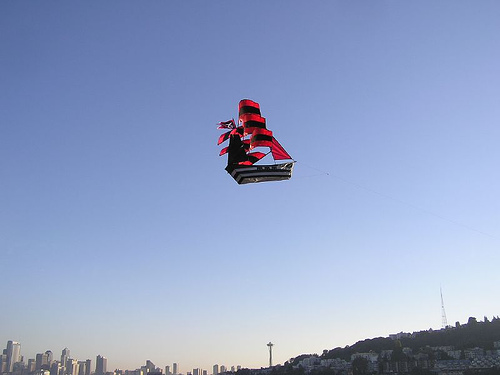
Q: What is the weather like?
A: It is clear.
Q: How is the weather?
A: It is clear.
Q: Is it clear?
A: Yes, it is clear.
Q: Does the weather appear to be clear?
A: Yes, it is clear.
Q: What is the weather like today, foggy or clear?
A: It is clear.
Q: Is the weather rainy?
A: No, it is clear.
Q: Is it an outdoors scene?
A: Yes, it is outdoors.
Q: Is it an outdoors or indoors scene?
A: It is outdoors.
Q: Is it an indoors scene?
A: No, it is outdoors.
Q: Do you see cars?
A: No, there are no cars.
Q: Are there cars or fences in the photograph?
A: No, there are no cars or fences.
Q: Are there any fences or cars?
A: No, there are no cars or fences.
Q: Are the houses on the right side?
A: Yes, the houses are on the right of the image.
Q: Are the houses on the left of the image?
A: No, the houses are on the right of the image.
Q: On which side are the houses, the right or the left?
A: The houses are on the right of the image.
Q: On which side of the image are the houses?
A: The houses are on the right of the image.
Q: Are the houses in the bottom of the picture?
A: Yes, the houses are in the bottom of the image.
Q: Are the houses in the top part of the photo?
A: No, the houses are in the bottom of the image.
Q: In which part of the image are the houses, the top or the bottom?
A: The houses are in the bottom of the image.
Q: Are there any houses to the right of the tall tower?
A: Yes, there are houses to the right of the tower.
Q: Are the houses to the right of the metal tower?
A: Yes, the houses are to the right of the tower.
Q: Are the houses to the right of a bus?
A: No, the houses are to the right of the tower.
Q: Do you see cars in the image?
A: No, there are no cars.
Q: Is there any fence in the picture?
A: No, there are no fences.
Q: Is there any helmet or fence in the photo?
A: No, there are no fences or helmets.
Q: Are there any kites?
A: Yes, there is a kite.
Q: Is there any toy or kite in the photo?
A: Yes, there is a kite.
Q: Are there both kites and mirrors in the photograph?
A: No, there is a kite but no mirrors.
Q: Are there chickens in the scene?
A: No, there are no chickens.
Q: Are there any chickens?
A: No, there are no chickens.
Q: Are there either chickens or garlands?
A: No, there are no chickens or garlands.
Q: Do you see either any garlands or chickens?
A: No, there are no chickens or garlands.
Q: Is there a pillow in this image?
A: No, there are no pillows.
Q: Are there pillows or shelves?
A: No, there are no pillows or shelves.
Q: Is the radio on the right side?
A: Yes, the radio is on the right of the image.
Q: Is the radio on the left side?
A: No, the radio is on the right of the image.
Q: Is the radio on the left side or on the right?
A: The radio is on the right of the image.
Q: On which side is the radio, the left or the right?
A: The radio is on the right of the image.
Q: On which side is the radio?
A: The radio is on the right of the image.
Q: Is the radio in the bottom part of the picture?
A: Yes, the radio is in the bottom of the image.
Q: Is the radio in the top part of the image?
A: No, the radio is in the bottom of the image.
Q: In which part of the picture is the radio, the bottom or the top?
A: The radio is in the bottom of the image.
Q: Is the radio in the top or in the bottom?
A: The radio is in the bottom of the image.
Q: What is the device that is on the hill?
A: The device is a radio.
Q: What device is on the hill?
A: The device is a radio.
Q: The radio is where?
A: The radio is on the hill.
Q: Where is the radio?
A: The radio is on the hill.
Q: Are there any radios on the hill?
A: Yes, there is a radio on the hill.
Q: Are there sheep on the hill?
A: No, there is a radio on the hill.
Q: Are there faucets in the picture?
A: No, there are no faucets.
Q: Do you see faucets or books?
A: No, there are no faucets or books.